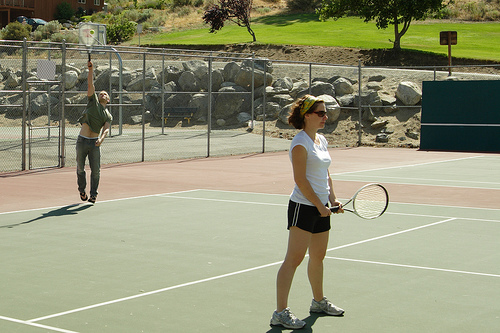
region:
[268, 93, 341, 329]
girl standing on tennis court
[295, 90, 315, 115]
green headband on girls head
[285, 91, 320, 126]
short brunette hair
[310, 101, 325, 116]
black sunglasses on girls face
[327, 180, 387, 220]
white tennis racket being held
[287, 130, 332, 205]
white tee shirt on girl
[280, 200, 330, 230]
white striped black shorts on girl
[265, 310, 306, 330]
gray sneaker on girl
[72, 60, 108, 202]
man swinging tennis racket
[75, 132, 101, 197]
dark jeans on man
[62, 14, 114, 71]
white tennis racket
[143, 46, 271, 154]
large rock retaining wal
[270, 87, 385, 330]
lady playing tennis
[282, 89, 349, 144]
lady with brown hair in headband and sun glasses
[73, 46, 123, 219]
young adult wearing jeans and green Tshirt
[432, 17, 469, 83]
rusty directional sign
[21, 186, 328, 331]
green tennis turf with white lines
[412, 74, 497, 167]
black tarp over wall divider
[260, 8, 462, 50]
green grass on hillside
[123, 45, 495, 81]
Dirt roadway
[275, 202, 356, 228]
the shorts are black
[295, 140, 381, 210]
the shirt is white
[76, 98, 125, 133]
the shirt is green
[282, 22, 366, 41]
the grass is green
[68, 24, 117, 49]
the ball is up in the air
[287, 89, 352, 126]
the headband is yellow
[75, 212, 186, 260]
the court is green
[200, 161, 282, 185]
the court is brown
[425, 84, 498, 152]
the wall is blue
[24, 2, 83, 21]
there is a building in the background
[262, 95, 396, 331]
Woman is standing on tennis court.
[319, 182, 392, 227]
Woman is holding tennis racquet.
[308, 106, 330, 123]
Woman is wearing sunglasses.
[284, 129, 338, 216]
Woman is wearing white shirt.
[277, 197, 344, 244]
Woman is wearing shorts.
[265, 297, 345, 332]
Woman is wearing tennis shoes.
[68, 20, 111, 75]
Man is hitting tennis ball.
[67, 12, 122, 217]
Man jumped in the air.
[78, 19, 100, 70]
Man is holding tennis racquet.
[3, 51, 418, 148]
Boulders on other side of fence.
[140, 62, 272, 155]
the pitch is fenced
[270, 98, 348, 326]
this is a woman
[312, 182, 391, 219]
the woman is holding a racket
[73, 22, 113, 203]
the man is jumping in the air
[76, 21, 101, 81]
the man's arm is raised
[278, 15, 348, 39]
this is the grass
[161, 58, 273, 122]
these are large stones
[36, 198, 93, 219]
this is the man's shadow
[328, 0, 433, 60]
this is a tree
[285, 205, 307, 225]
this is a black pair of shorts